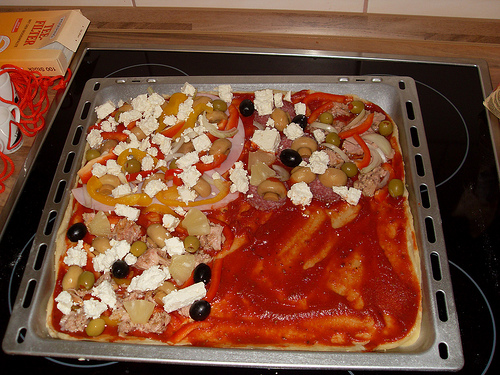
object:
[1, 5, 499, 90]
trim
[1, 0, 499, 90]
wall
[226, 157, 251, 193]
cheese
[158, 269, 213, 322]
cheese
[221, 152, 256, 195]
cheese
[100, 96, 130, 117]
cheese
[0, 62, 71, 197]
string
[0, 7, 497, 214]
counter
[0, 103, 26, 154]
mugs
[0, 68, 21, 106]
mugs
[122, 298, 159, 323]
pineapple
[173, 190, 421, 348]
pizza sauce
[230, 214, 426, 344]
sauce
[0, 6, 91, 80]
box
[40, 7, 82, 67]
filters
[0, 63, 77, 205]
red string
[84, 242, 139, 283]
cheese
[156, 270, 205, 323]
cheese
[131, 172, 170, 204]
cheese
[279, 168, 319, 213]
cheese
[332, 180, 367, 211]
cheese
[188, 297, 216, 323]
olive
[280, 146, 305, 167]
olive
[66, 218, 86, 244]
olive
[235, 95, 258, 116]
olive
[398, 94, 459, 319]
pan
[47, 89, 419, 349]
sauce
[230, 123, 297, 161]
cheese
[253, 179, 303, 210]
mushroom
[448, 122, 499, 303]
stove top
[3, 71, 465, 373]
pan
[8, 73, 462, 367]
tray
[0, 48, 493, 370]
stove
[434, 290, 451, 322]
hole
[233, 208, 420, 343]
tomato sauce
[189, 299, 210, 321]
olive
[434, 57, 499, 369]
electric stove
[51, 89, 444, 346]
pizza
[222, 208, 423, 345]
crust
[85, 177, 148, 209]
pepper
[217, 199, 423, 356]
section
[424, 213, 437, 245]
holes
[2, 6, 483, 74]
wood